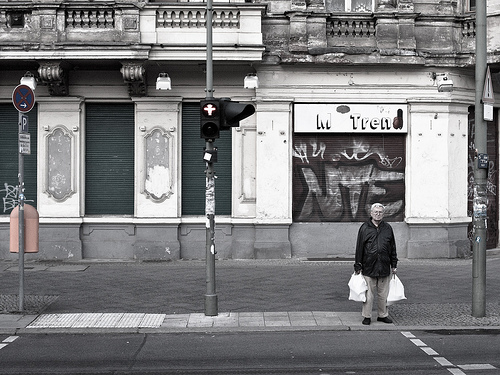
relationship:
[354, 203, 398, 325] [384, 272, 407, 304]
gentleman bringing food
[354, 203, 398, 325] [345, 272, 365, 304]
gentleman bringing food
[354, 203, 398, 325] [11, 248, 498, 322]
gentleman standing on sidewalk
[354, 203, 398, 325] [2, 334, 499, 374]
gentleman standing near street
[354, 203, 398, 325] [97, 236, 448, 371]
gentleman standing near street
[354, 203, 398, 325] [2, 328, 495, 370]
gentleman standing near street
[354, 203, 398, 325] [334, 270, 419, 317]
gentleman holding bags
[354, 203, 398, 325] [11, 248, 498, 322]
gentleman standing near sidewalk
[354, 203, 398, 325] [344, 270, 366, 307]
gentleman with bags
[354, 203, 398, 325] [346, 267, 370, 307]
gentleman with bags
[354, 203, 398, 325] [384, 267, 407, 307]
gentleman with bags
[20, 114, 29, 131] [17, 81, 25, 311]
sign on metallic pole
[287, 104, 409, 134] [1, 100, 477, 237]
sign on shop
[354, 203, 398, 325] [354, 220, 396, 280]
gentleman wears coat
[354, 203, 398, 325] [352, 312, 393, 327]
gentleman wears shoes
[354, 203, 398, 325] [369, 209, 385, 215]
gentleman wears glasses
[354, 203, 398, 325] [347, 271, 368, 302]
gentleman carry bag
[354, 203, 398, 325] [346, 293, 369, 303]
gentleman carry white bag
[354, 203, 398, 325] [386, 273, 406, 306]
gentleman carry bag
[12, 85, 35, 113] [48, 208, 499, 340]
sign on sidewalk.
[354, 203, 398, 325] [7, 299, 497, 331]
gentleman on sidewalk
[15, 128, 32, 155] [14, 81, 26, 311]
sign on metallic pole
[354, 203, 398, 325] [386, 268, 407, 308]
gentleman carrying bag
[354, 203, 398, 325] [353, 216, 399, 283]
gentleman wearing coat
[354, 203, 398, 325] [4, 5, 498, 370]
gentleman in city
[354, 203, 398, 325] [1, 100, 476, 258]
gentleman visited shop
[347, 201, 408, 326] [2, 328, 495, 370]
gentleman near street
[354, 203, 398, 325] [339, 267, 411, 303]
gentleman holding bags